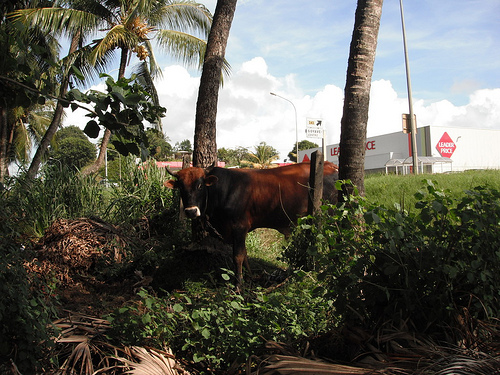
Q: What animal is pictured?
A: A bull.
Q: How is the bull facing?
A: Forward.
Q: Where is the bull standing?
A: Between the trees.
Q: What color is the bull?
A: Brown.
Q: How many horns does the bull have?
A: Two.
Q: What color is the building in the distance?
A: White.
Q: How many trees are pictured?
A: Five.